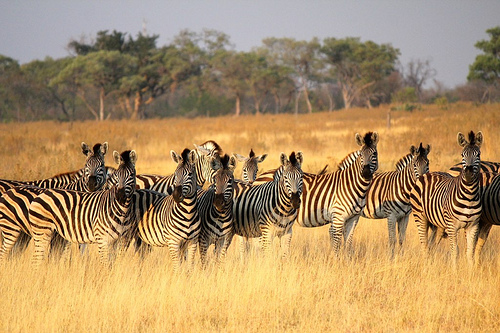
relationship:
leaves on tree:
[0, 30, 428, 128] [0, 30, 400, 116]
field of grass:
[10, 90, 460, 330] [75, 260, 416, 328]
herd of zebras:
[0, 120, 480, 274] [0, 124, 481, 260]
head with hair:
[349, 126, 385, 188] [337, 150, 362, 171]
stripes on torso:
[289, 145, 368, 247] [293, 158, 342, 226]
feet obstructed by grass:
[0, 240, 467, 280] [0, 108, 476, 329]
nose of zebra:
[362, 164, 373, 184] [307, 136, 387, 254]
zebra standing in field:
[414, 139, 488, 259] [275, 237, 486, 322]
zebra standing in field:
[410, 131, 485, 274] [12, 249, 498, 328]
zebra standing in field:
[373, 134, 430, 251] [4, 240, 480, 330]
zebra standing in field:
[311, 129, 381, 246] [4, 240, 480, 330]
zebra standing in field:
[236, 153, 306, 251] [4, 240, 480, 330]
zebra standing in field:
[235, 148, 265, 183] [12, 249, 498, 328]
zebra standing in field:
[209, 156, 231, 264] [4, 240, 480, 330]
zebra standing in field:
[136, 147, 198, 258] [4, 240, 480, 330]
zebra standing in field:
[27, 149, 138, 277] [6, 232, 497, 313]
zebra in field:
[18, 143, 150, 249] [73, 253, 188, 294]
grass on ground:
[169, 285, 252, 308] [200, 255, 288, 286]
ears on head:
[451, 129, 488, 149] [455, 143, 486, 180]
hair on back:
[335, 151, 361, 172] [307, 162, 355, 189]